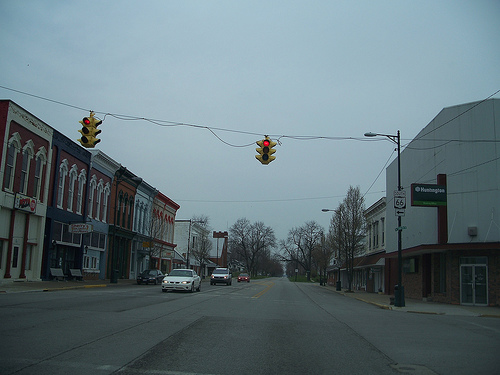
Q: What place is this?
A: It is a road.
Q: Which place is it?
A: It is a road.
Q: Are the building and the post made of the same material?
A: No, the building is made of cement and the post is made of metal.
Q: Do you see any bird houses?
A: No, there are no bird houses.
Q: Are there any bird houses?
A: No, there are no bird houses.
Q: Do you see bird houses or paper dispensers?
A: No, there are no bird houses or paper dispensers.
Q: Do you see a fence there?
A: No, there are no fences.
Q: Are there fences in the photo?
A: No, there are no fences.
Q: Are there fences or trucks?
A: No, there are no fences or trucks.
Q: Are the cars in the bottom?
A: Yes, the cars are in the bottom of the image.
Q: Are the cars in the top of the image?
A: No, the cars are in the bottom of the image.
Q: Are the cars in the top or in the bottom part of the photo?
A: The cars are in the bottom of the image.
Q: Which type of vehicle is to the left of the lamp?
A: The vehicles are cars.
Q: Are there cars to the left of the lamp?
A: Yes, there are cars to the left of the lamp.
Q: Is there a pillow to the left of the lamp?
A: No, there are cars to the left of the lamp.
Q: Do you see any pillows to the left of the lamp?
A: No, there are cars to the left of the lamp.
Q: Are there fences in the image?
A: No, there are no fences.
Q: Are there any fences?
A: No, there are no fences.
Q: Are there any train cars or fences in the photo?
A: No, there are no fences or train cars.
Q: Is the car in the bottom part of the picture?
A: Yes, the car is in the bottom of the image.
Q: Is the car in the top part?
A: No, the car is in the bottom of the image.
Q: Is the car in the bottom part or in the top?
A: The car is in the bottom of the image.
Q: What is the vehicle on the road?
A: The vehicle is a car.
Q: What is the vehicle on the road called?
A: The vehicle is a car.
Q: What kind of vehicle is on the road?
A: The vehicle is a car.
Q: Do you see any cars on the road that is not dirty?
A: Yes, there is a car on the road.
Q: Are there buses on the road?
A: No, there is a car on the road.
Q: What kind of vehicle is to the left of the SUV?
A: The vehicle is a car.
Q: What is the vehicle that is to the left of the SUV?
A: The vehicle is a car.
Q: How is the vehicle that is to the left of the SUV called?
A: The vehicle is a car.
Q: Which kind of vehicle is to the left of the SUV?
A: The vehicle is a car.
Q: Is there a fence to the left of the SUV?
A: No, there is a car to the left of the SUV.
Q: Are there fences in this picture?
A: No, there are no fences.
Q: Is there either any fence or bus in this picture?
A: No, there are no fences or buses.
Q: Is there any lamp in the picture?
A: Yes, there is a lamp.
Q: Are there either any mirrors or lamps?
A: Yes, there is a lamp.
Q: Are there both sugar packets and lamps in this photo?
A: No, there is a lamp but no sugar packets.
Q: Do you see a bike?
A: No, there are no bikes.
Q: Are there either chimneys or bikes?
A: No, there are no bikes or chimneys.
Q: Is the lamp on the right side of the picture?
A: Yes, the lamp is on the right of the image.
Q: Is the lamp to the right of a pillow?
A: No, the lamp is to the right of a car.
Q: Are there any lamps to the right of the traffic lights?
A: Yes, there is a lamp to the right of the traffic lights.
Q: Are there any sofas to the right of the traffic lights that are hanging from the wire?
A: No, there is a lamp to the right of the traffic lights.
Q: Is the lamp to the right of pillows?
A: No, the lamp is to the right of the traffic lights.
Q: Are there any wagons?
A: No, there are no wagons.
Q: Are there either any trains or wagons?
A: No, there are no wagons or trains.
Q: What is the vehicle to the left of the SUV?
A: The vehicle is a car.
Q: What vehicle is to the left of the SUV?
A: The vehicle is a car.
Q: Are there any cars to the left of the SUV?
A: Yes, there is a car to the left of the SUV.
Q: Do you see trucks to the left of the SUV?
A: No, there is a car to the left of the SUV.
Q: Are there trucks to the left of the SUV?
A: No, there is a car to the left of the SUV.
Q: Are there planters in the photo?
A: No, there are no planters.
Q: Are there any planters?
A: No, there are no planters.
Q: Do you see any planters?
A: No, there are no planters.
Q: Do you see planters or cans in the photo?
A: No, there are no planters or cans.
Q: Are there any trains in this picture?
A: No, there are no trains.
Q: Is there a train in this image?
A: No, there are no trains.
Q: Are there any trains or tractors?
A: No, there are no trains or tractors.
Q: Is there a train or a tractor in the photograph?
A: No, there are no trains or tractors.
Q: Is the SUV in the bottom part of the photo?
A: Yes, the SUV is in the bottom of the image.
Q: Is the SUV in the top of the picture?
A: No, the SUV is in the bottom of the image.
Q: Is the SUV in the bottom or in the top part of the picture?
A: The SUV is in the bottom of the image.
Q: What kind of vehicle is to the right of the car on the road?
A: The vehicle is a SUV.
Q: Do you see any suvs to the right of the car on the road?
A: Yes, there is a SUV to the right of the car.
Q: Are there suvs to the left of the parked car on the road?
A: No, the SUV is to the right of the car.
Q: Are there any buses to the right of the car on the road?
A: No, there is a SUV to the right of the car.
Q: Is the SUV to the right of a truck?
A: No, the SUV is to the right of the car.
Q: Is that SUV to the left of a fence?
A: No, the SUV is to the left of the car.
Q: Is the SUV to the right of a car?
A: No, the SUV is to the left of a car.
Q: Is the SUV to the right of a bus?
A: No, the SUV is to the right of the car.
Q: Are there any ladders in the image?
A: No, there are no ladders.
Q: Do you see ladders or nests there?
A: No, there are no ladders or nests.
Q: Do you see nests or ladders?
A: No, there are no ladders or nests.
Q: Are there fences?
A: No, there are no fences.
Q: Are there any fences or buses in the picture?
A: No, there are no fences or buses.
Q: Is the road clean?
A: Yes, the road is clean.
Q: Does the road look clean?
A: Yes, the road is clean.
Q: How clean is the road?
A: The road is clean.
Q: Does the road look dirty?
A: No, the road is clean.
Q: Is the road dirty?
A: No, the road is clean.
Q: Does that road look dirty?
A: No, the road is clean.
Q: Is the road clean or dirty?
A: The road is clean.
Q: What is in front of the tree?
A: The road is in front of the tree.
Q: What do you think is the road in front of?
A: The road is in front of the tree.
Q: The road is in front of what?
A: The road is in front of the tree.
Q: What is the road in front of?
A: The road is in front of the tree.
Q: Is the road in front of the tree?
A: Yes, the road is in front of the tree.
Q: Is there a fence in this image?
A: No, there are no fences.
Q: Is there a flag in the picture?
A: No, there are no flags.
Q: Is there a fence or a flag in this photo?
A: No, there are no flags or fences.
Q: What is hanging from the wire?
A: The traffic lights are hanging from the wire.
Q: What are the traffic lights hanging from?
A: The traffic lights are hanging from the wire.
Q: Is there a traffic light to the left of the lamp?
A: Yes, there are traffic lights to the left of the lamp.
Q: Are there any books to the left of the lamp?
A: No, there are traffic lights to the left of the lamp.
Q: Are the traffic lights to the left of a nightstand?
A: No, the traffic lights are to the left of the lamp.